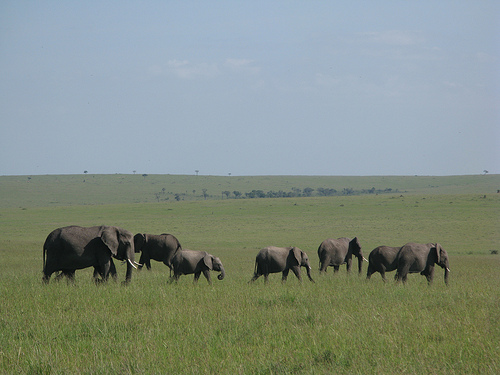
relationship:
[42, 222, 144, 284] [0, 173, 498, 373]
adult on field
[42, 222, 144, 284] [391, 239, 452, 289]
adult has baby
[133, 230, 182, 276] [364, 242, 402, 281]
elephant has baby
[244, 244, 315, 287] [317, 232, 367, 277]
baby has baby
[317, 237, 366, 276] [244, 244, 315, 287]
baby has baby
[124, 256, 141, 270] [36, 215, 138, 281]
tusk of elephant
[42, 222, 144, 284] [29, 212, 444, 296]
adult walking with each other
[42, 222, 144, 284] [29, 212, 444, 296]
adult among each other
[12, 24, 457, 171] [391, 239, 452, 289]
sky above baby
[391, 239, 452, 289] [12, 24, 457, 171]
baby below sky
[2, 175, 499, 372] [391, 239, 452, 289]
grass beneath baby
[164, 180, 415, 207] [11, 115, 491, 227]
trees growing in background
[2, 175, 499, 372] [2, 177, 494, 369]
grass in fields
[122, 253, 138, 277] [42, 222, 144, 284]
trunks on adult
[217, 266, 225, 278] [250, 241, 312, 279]
trunks on elephant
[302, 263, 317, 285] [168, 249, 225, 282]
trunks on baby elephant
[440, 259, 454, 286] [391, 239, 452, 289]
trunks on baby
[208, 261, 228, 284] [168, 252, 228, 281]
trunk on elephant